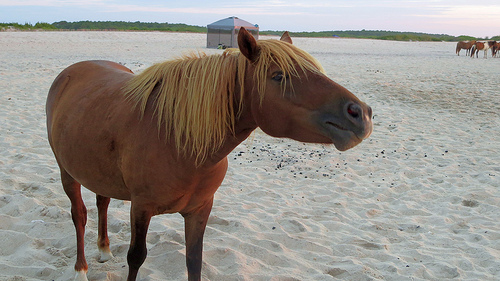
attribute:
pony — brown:
[31, 21, 378, 280]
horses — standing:
[449, 35, 499, 61]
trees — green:
[4, 18, 205, 32]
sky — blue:
[0, 0, 499, 22]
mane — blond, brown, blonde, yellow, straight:
[134, 41, 303, 158]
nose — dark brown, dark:
[340, 94, 370, 123]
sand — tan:
[3, 27, 499, 280]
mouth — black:
[327, 114, 367, 145]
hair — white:
[74, 268, 89, 280]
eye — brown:
[271, 72, 291, 83]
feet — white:
[71, 246, 121, 281]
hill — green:
[2, 14, 466, 33]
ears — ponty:
[232, 21, 299, 60]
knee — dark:
[125, 240, 151, 268]